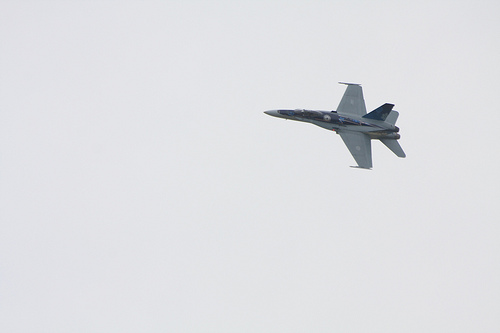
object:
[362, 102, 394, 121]
tail fin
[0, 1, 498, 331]
sky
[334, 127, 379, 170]
wing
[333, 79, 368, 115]
wing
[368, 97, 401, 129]
wing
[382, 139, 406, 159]
wing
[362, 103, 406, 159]
tail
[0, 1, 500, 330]
cloudy sky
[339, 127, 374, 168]
wings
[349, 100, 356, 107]
logo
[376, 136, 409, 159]
wing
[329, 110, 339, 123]
design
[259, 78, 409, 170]
aircraft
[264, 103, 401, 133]
back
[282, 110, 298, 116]
cockpit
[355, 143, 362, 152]
design